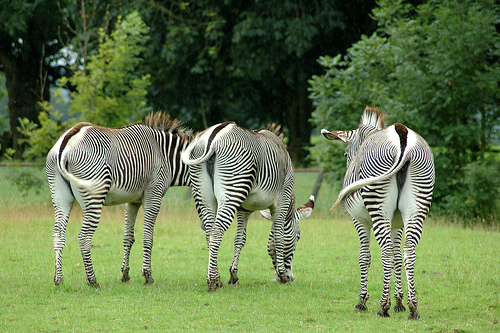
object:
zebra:
[43, 109, 196, 290]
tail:
[179, 133, 218, 167]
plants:
[0, 9, 155, 200]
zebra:
[180, 120, 315, 293]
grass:
[0, 276, 499, 331]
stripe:
[392, 124, 410, 152]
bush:
[431, 128, 499, 224]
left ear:
[318, 128, 350, 148]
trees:
[150, 0, 320, 168]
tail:
[52, 143, 102, 198]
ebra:
[318, 106, 437, 321]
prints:
[81, 133, 103, 166]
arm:
[270, 176, 295, 285]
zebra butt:
[43, 125, 107, 205]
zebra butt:
[187, 123, 253, 200]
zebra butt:
[361, 125, 433, 212]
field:
[2, 263, 352, 329]